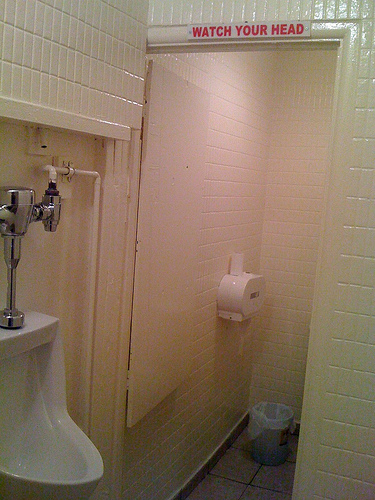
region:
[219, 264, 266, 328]
white metal toilet paper roll holder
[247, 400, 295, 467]
blue waste can with plastic bag inside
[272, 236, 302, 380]
white tiles on wall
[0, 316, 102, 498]
white porcelain urinal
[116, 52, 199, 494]
open stall door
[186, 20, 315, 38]
white sign with red letter WATCH YOUR HEAD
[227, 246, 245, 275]
roll of white toilet paper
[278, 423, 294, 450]
label on waste can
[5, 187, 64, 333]
chrome fixture on urinal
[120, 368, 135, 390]
hinge on stall door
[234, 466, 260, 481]
floor of a washroom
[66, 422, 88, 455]
part of a latrine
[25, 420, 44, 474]
section of a sink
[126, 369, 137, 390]
section of a door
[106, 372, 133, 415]
hinge of a door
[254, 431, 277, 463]
part of a dust bin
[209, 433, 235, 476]
edge of a wall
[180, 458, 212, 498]
bottom part of a wall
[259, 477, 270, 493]
tiles of a toilet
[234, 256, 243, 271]
white tissue in a toilet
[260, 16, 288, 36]
part of a notice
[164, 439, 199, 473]
part of a wall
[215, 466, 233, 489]
part of a floor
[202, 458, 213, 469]
edge of a wall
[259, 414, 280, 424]
edge of a bin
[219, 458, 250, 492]
part of a floor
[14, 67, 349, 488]
A white bathroom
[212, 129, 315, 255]
White tiles on a bathroom wall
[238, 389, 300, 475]
A trashcan with a white bag liner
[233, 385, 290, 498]
A trash can on a tile floor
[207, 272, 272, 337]
a white toilet paper holder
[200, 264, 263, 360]
a white toilet paper holder on a tile wall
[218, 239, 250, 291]
A roll of toilet paper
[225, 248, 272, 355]
A roll of toilet paper on top of a holder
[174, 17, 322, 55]
A sign on a door frame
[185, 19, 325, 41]
Red letters on a sign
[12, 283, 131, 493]
A white urinal in a bathroom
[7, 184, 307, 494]
A white tile bathroom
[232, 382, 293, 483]
a trash can on the floor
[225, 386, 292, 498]
a trash can on a tile floor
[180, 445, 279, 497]
A tile bathroom floor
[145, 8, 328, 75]
Red letters on a white sign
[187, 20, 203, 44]
A red letter "W"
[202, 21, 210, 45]
A red letter "A"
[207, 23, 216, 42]
A red letter "T"